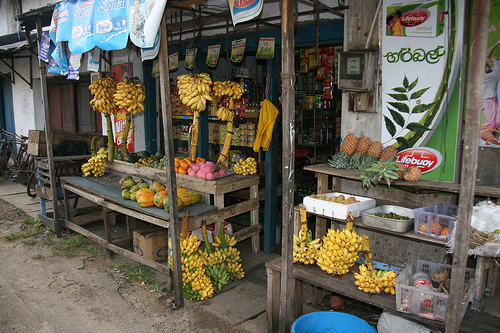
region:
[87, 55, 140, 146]
bundles of banana hanging from a hook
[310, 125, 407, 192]
four pineapples on a shelf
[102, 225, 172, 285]
card board box on the ground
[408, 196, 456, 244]
a plastic tub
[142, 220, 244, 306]
several bundles of bananas on the ground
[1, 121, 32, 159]
a bike parked next to a building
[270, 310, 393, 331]
a blue plastic tub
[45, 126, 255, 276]
wooden shelves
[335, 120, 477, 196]
pineapples on a shelf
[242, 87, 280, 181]
yellow plastic bags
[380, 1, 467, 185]
poster advertisement for 'lifebuoy herbal' soap, which is largely sold in the third world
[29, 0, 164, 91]
curling turquoise posters for 'signal' toothpaste, ibid, aka 'pepsodent' in the US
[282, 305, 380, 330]
a turquoise blue bucket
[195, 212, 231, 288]
yellow bananas, green bananas on long stems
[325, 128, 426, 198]
six pineapples, one w/o leaves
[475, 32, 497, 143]
a woman wearing pink pants on a soap poster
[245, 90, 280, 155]
bright yellow orange bags, hanging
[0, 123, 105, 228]
black bicycle behind boxes+crates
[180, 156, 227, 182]
pink fruit, possibly pomegranate, possibly ackee, possibly neither but pretty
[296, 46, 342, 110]
many small packaged food items hanging inside the shop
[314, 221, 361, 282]
the bananas are yellow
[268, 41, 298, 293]
the pole is wooden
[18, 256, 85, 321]
the ground is brown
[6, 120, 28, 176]
the bike is leaning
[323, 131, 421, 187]
the pineapples are ripe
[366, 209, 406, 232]
the basket is white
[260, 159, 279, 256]
the pole is blue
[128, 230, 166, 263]
the box is brown and cardboard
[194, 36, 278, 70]
the banners are hanging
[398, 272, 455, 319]
the basket is big and clear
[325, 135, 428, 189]
pineapples on shelf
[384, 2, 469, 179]
poster on wall of market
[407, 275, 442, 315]
empty soda bottle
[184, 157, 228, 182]
pink fruits on shelf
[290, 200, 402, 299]
banana bunches on shelf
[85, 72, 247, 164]
banana bunches hanging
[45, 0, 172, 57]
banner hanging from porch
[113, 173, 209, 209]
melons sitting on shelf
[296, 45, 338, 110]
packages of product hanging in shop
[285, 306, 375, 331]
blue pail on ground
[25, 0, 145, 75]
blue kitchen products hanging from top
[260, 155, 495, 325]
brown wooden shelves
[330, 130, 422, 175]
pineapples on top row of shelves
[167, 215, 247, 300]
pile of yellow squash leaning against shelves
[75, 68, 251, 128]
bananas hanging from top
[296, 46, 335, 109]
small yellow and orange bags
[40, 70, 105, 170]
wooden doors to the left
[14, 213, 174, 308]
small grass patches on dirt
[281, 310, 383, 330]
partial view of blue bucket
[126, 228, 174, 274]
cardboard box under shelves